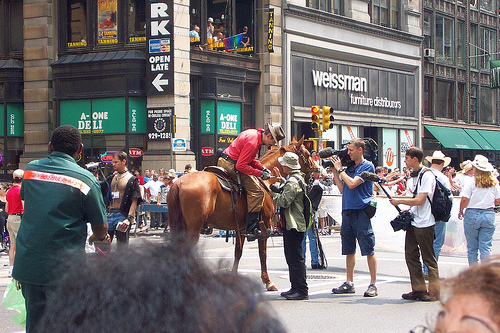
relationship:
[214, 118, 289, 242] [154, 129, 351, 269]
guy riding horse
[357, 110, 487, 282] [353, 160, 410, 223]
guy holding mic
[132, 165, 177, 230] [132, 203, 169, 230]
people standing behind barricade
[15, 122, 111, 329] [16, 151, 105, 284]
guy wearing shirt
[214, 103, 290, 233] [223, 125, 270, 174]
guy wearing shirt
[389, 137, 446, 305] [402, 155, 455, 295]
guy carrying backpack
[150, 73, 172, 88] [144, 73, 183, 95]
arrow on sign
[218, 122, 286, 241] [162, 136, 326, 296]
guy riding horse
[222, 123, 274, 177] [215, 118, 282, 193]
man wearing man shirt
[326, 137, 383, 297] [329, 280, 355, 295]
man wearing shoe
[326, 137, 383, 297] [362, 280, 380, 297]
man wearing shoe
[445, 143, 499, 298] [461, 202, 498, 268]
woman wearing jeans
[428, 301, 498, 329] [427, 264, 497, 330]
eyebrows of woman